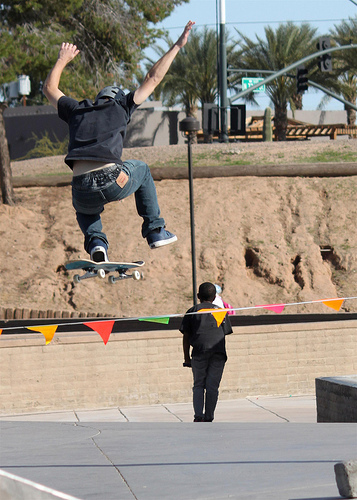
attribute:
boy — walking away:
[177, 274, 233, 423]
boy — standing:
[180, 282, 232, 427]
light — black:
[227, 99, 248, 133]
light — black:
[297, 66, 308, 94]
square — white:
[118, 405, 182, 421]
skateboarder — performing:
[42, 12, 196, 255]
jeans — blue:
[63, 177, 112, 252]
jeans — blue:
[71, 159, 179, 261]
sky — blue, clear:
[1, 0, 354, 107]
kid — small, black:
[174, 267, 250, 421]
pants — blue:
[68, 158, 165, 251]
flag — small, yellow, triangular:
[28, 315, 58, 349]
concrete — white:
[8, 413, 316, 496]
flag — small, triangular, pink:
[256, 298, 290, 315]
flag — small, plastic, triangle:
[133, 314, 173, 331]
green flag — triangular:
[132, 285, 193, 354]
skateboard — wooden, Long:
[66, 254, 154, 286]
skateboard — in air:
[48, 200, 147, 292]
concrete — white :
[120, 399, 295, 429]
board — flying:
[54, 256, 146, 287]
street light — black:
[205, 103, 238, 137]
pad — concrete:
[191, 396, 273, 434]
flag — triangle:
[270, 303, 284, 314]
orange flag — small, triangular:
[318, 294, 355, 313]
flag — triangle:
[254, 289, 306, 330]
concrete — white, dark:
[0, 394, 357, 498]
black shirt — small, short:
[179, 301, 236, 361]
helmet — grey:
[95, 82, 127, 98]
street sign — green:
[238, 73, 273, 97]